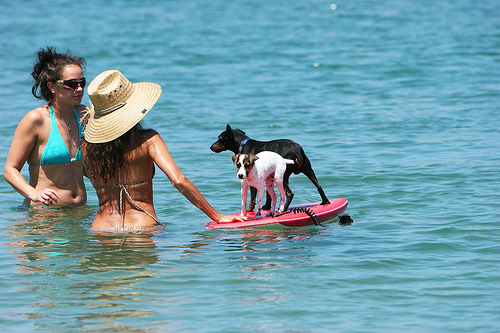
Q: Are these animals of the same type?
A: Yes, all the animals are dogs.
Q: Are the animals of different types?
A: No, all the animals are dogs.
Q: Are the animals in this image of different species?
A: No, all the animals are dogs.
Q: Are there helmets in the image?
A: No, there are no helmets.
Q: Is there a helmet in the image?
A: No, there are no helmets.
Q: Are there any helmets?
A: No, there are no helmets.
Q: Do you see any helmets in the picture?
A: No, there are no helmets.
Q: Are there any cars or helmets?
A: No, there are no helmets or cars.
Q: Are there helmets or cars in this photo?
A: No, there are no helmets or cars.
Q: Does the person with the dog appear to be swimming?
A: Yes, the person is swimming.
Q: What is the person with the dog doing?
A: The person is swimming.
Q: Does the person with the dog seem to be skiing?
A: No, the person is swimming.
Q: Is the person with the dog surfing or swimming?
A: The person is swimming.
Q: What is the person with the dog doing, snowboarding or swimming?
A: The person is swimming.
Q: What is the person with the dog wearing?
A: The person is wearing a hat.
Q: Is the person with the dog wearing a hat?
A: Yes, the person is wearing a hat.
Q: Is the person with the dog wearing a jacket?
A: No, the person is wearing a hat.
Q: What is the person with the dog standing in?
A: The person is standing in the water.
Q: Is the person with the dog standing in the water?
A: Yes, the person is standing in the water.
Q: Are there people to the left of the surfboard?
A: Yes, there is a person to the left of the surfboard.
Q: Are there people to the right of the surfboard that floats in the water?
A: No, the person is to the left of the surfboard.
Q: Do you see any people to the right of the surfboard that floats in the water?
A: No, the person is to the left of the surfboard.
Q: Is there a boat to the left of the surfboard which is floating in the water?
A: No, there is a person to the left of the surfboard.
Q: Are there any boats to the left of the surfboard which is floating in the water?
A: No, there is a person to the left of the surfboard.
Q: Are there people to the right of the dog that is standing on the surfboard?
A: No, the person is to the left of the dog.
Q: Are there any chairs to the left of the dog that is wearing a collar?
A: No, there is a person to the left of the dog.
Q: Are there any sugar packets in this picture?
A: No, there are no sugar packets.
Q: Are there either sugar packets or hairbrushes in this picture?
A: No, there are no sugar packets or hairbrushes.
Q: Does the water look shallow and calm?
A: Yes, the water is shallow and calm.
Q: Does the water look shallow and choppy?
A: No, the water is shallow but calm.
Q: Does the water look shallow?
A: Yes, the water is shallow.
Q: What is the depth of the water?
A: The water is shallow.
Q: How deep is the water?
A: The water is shallow.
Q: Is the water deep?
A: No, the water is shallow.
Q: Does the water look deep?
A: No, the water is shallow.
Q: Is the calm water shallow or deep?
A: The water is shallow.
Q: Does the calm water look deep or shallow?
A: The water is shallow.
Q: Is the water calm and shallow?
A: Yes, the water is calm and shallow.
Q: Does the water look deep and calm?
A: No, the water is calm but shallow.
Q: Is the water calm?
A: Yes, the water is calm.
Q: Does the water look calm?
A: Yes, the water is calm.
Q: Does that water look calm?
A: Yes, the water is calm.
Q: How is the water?
A: The water is calm.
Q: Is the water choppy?
A: No, the water is calm.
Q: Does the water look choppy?
A: No, the water is calm.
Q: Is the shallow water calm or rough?
A: The water is calm.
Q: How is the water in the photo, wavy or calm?
A: The water is calm.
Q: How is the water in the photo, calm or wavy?
A: The water is calm.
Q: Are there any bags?
A: No, there are no bags.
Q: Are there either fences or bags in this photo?
A: No, there are no bags or fences.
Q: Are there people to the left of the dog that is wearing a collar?
A: Yes, there is a person to the left of the dog.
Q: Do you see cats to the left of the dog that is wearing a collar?
A: No, there is a person to the left of the dog.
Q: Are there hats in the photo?
A: Yes, there is a hat.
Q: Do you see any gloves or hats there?
A: Yes, there is a hat.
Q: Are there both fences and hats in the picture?
A: No, there is a hat but no fences.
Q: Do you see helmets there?
A: No, there are no helmets.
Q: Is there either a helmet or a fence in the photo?
A: No, there are no helmets or fences.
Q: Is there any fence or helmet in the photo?
A: No, there are no helmets or fences.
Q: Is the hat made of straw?
A: Yes, the hat is made of straw.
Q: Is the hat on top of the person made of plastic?
A: No, the hat is made of straw.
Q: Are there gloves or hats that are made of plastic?
A: No, there is a hat but it is made of straw.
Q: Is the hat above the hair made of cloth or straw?
A: The hat is made of straw.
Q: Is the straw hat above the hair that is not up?
A: Yes, the hat is above the hair.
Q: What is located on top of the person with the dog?
A: The hat is on top of the person.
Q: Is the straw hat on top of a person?
A: Yes, the hat is on top of a person.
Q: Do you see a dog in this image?
A: Yes, there is a dog.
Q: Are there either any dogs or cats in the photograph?
A: Yes, there is a dog.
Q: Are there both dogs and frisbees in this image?
A: No, there is a dog but no frisbees.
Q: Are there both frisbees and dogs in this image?
A: No, there is a dog but no frisbees.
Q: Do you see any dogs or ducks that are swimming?
A: Yes, the dog is swimming.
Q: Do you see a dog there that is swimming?
A: Yes, there is a dog that is swimming.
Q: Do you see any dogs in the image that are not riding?
A: Yes, there is a dog that is swimming .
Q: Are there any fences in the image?
A: No, there are no fences.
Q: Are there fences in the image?
A: No, there are no fences.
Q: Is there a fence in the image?
A: No, there are no fences.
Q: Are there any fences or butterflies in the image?
A: No, there are no fences or butterflies.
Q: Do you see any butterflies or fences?
A: No, there are no fences or butterflies.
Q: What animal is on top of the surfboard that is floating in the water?
A: The dog is on top of the surfboard.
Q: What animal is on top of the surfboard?
A: The dog is on top of the surfboard.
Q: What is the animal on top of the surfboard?
A: The animal is a dog.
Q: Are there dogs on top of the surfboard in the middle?
A: Yes, there is a dog on top of the surf board.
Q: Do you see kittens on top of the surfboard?
A: No, there is a dog on top of the surfboard.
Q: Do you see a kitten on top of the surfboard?
A: No, there is a dog on top of the surfboard.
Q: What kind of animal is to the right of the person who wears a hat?
A: The animal is a dog.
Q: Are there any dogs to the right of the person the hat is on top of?
A: Yes, there is a dog to the right of the person.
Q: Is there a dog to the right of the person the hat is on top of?
A: Yes, there is a dog to the right of the person.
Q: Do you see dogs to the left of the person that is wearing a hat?
A: No, the dog is to the right of the person.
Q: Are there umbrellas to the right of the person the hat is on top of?
A: No, there is a dog to the right of the person.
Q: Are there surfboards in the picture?
A: Yes, there is a surfboard.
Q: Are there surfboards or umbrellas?
A: Yes, there is a surfboard.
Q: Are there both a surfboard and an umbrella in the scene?
A: No, there is a surfboard but no umbrellas.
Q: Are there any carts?
A: No, there are no carts.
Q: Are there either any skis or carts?
A: No, there are no carts or skis.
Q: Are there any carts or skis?
A: No, there are no carts or skis.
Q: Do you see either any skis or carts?
A: No, there are no carts or skis.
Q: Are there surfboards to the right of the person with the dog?
A: Yes, there is a surfboard to the right of the person.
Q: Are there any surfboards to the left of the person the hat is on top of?
A: No, the surfboard is to the right of the person.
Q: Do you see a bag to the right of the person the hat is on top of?
A: No, there is a surfboard to the right of the person.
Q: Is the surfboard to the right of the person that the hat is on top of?
A: Yes, the surfboard is to the right of the person.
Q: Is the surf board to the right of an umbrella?
A: No, the surf board is to the right of the person.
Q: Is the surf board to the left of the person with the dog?
A: No, the surf board is to the right of the person.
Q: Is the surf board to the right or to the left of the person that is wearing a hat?
A: The surf board is to the right of the person.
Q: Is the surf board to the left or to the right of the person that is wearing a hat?
A: The surf board is to the right of the person.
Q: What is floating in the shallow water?
A: The surf board is floating in the water.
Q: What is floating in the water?
A: The surf board is floating in the water.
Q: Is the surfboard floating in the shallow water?
A: Yes, the surfboard is floating in the water.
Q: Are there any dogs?
A: Yes, there is a dog.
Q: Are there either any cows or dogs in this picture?
A: Yes, there is a dog.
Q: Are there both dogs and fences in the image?
A: No, there is a dog but no fences.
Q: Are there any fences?
A: No, there are no fences.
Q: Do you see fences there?
A: No, there are no fences.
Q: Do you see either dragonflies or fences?
A: No, there are no fences or dragonflies.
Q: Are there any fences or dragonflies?
A: No, there are no fences or dragonflies.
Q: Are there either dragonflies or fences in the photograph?
A: No, there are no fences or dragonflies.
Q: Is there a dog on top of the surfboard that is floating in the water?
A: Yes, there is a dog on top of the surfboard.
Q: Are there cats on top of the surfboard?
A: No, there is a dog on top of the surfboard.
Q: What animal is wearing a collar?
A: The dog is wearing a collar.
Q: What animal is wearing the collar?
A: The dog is wearing a collar.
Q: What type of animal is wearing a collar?
A: The animal is a dog.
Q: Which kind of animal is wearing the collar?
A: The animal is a dog.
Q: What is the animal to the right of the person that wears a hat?
A: The animal is a dog.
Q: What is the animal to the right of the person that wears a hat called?
A: The animal is a dog.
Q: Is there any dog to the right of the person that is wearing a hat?
A: Yes, there is a dog to the right of the person.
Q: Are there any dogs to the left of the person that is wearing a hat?
A: No, the dog is to the right of the person.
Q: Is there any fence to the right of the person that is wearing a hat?
A: No, there is a dog to the right of the person.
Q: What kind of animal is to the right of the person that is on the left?
A: The animal is a dog.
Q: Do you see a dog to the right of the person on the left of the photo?
A: Yes, there is a dog to the right of the person.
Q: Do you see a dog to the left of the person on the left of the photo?
A: No, the dog is to the right of the person.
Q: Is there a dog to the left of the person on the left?
A: No, the dog is to the right of the person.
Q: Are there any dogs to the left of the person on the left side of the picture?
A: No, the dog is to the right of the person.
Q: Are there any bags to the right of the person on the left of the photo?
A: No, there is a dog to the right of the person.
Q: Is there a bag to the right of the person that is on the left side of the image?
A: No, there is a dog to the right of the person.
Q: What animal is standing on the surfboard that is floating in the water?
A: The dog is standing on the surf board.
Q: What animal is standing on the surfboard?
A: The dog is standing on the surf board.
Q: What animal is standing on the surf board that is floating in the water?
A: The animal is a dog.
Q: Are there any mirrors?
A: No, there are no mirrors.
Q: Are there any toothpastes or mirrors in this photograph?
A: No, there are no mirrors or toothpastes.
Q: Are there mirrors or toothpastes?
A: No, there are no mirrors or toothpastes.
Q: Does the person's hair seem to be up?
A: No, the hair is down.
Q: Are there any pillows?
A: No, there are no pillows.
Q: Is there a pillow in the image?
A: No, there are no pillows.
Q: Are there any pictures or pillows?
A: No, there are no pillows or pictures.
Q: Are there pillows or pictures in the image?
A: No, there are no pillows or pictures.